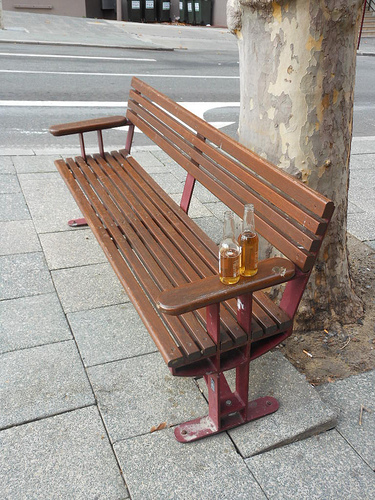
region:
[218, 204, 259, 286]
a couple of bottles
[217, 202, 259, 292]
bottles on a bench arm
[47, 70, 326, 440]
a wooden bench seat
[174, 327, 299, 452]
red metal on a bench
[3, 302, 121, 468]
gray concrete on the ground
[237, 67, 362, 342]
a tree behind the bench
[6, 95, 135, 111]
a line on a road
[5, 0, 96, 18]
a tan concrete wall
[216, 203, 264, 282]
brown liquid in bottles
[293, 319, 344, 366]
cigarette butts on the ground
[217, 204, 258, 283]
Two open bottles of beer on an armrest.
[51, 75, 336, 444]
A bench parked in front of a chair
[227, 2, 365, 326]
The trunk of a tree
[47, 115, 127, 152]
The arm rest of a bench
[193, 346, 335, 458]
A stone slab lifting out of the ground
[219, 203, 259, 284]
Two beer bottles sitting outside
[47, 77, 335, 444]
A brown bench by the street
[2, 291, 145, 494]
Cement slabs on the ground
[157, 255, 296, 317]
Arm rest of a park bench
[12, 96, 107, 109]
Painted stripe on a street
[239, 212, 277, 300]
Beer bottle on ledge of bench.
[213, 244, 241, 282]
Beer bottle on ledge of bench.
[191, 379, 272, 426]
Red foot on bench.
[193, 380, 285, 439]
Metal foot on bench.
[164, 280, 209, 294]
Wood arm rest on bench.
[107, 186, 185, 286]
Seat on bench is wood.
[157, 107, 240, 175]
Back of bench is wood.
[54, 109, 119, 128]
Wood arm rest on bench.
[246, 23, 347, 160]
Large tree behind bench.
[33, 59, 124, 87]
White line marking pavement.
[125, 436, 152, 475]
part of a floor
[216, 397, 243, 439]
part of a stand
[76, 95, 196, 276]
this is a bench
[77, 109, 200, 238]
thee bench is wooden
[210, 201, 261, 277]
these are bottles of wine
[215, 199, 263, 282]
the bottles are half full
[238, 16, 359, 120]
this is a tree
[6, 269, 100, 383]
the floor is clean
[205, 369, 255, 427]
this is the leg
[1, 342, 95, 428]
a stone in the floor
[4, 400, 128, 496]
a stone in the floor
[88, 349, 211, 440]
a stone in the floor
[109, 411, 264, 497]
a stone in the floor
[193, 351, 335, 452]
a stone in the floor